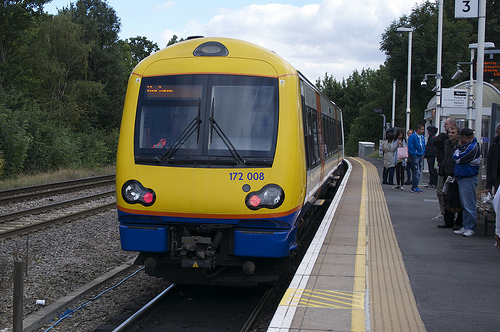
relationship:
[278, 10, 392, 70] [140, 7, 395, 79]
cloud in sky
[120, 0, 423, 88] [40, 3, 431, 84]
cloud in sky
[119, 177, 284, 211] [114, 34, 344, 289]
headlights on train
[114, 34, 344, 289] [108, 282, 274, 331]
train on tracks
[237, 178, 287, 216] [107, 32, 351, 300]
headlight on train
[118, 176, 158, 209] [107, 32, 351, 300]
headlight on train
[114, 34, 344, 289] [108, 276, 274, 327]
train on tracks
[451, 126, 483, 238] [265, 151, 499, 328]
people on train platform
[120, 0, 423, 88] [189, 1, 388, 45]
cloud in sky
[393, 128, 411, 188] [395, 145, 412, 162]
woman holds pink bag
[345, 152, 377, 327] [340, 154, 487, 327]
stripe on sidewalk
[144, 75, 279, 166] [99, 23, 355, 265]
windows on train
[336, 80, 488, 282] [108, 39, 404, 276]
people wait train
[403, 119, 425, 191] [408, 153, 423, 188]
man wears blue jeans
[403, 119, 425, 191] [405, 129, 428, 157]
man wears blue jacket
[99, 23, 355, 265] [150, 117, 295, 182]
train has windshield wipers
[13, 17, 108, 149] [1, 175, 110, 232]
trees along tracks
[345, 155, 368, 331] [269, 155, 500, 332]
stripe on platform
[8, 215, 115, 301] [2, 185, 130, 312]
gravel on ground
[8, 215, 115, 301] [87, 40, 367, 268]
gravel surrounding train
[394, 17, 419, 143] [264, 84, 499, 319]
pole at station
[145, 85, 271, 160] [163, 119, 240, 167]
windshield has wipers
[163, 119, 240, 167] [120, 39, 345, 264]
wipers on train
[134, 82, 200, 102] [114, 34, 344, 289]
window atop train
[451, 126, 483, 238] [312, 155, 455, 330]
people on platform